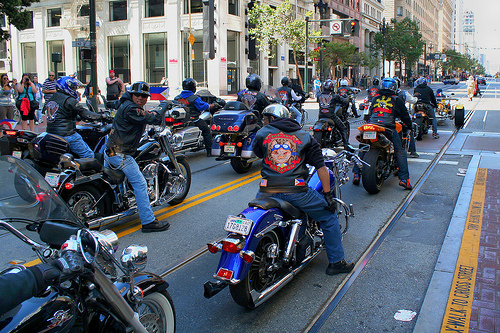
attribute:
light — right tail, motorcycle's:
[234, 245, 265, 270]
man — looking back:
[98, 81, 173, 233]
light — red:
[196, 223, 266, 277]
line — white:
[407, 149, 463, 171]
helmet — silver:
[261, 100, 291, 121]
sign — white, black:
[322, 10, 346, 42]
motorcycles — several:
[27, 71, 449, 274]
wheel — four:
[226, 222, 285, 311]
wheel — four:
[158, 157, 193, 205]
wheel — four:
[363, 145, 393, 197]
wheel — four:
[228, 139, 254, 174]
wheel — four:
[44, 177, 121, 232]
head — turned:
[127, 83, 150, 109]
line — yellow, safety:
[439, 167, 489, 331]